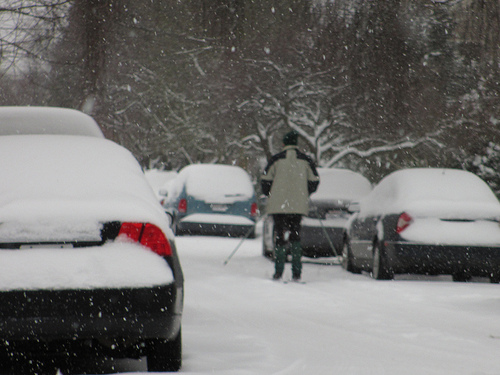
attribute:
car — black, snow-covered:
[6, 134, 186, 373]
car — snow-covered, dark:
[344, 162, 499, 282]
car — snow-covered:
[267, 167, 373, 263]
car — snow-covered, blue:
[158, 157, 263, 239]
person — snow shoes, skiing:
[259, 128, 322, 281]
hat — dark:
[281, 129, 300, 148]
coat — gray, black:
[252, 150, 322, 222]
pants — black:
[264, 219, 304, 269]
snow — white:
[6, 110, 498, 373]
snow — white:
[2, 86, 498, 364]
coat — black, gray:
[257, 148, 318, 218]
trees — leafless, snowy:
[2, 6, 489, 187]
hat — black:
[279, 124, 299, 145]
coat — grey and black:
[258, 145, 321, 211]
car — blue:
[166, 161, 259, 237]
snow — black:
[1, 240, 174, 293]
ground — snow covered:
[176, 233, 498, 373]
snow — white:
[176, 233, 496, 373]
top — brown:
[259, 146, 320, 212]